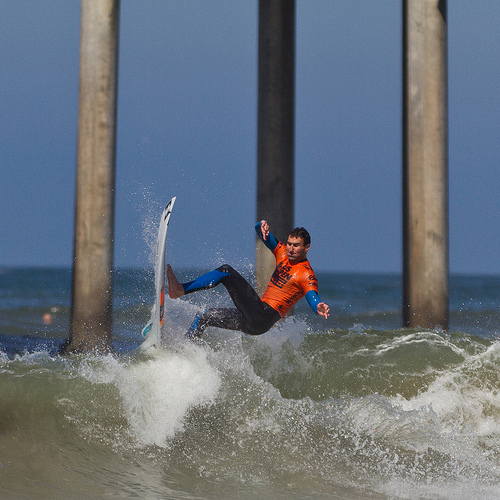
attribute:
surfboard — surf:
[148, 188, 177, 340]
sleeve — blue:
[307, 290, 320, 305]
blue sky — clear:
[123, 11, 253, 193]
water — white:
[2, 266, 498, 498]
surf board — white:
[128, 197, 190, 368]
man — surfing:
[166, 217, 331, 334]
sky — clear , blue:
[127, 10, 245, 197]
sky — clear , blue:
[7, 0, 70, 213]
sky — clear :
[308, 7, 398, 191]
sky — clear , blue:
[453, 14, 492, 225]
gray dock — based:
[61, 0, 499, 368]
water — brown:
[13, 354, 376, 486]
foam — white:
[109, 357, 187, 430]